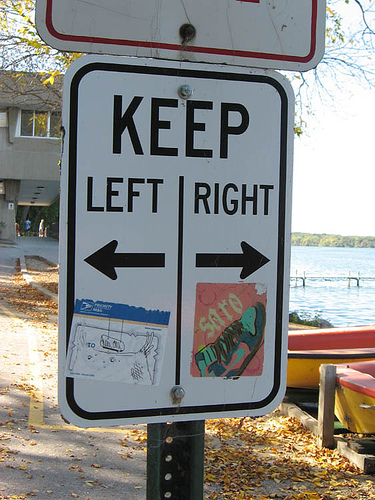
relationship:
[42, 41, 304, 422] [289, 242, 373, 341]
sign near water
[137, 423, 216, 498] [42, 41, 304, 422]
pole holding sign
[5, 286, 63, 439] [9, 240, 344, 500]
lines on ground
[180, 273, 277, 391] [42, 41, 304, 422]
sticker on sign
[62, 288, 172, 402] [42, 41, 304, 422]
sticker on sign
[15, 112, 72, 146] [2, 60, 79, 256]
window on building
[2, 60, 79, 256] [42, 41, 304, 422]
building behind sign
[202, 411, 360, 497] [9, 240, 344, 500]
leaves on ground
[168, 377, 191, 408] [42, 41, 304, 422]
bolt on sign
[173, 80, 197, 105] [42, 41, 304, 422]
bolt on sign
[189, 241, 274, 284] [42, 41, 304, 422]
arrow on sign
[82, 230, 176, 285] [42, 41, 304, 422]
arrow on sign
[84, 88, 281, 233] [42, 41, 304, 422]
letters on sign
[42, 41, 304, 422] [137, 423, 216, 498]
sign on post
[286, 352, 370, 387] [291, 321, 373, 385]
paint on boat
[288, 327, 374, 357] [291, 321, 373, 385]
paint on boat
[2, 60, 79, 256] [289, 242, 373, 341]
house on lake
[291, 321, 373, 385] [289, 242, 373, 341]
boat in water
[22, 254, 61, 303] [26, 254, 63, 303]
leaves in sand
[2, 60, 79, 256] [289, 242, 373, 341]
house by lake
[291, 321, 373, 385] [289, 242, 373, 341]
boat on lake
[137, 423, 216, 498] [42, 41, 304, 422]
pole on sign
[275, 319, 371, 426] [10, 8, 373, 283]
boats in background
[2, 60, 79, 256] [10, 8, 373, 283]
building in background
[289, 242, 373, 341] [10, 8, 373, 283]
water in background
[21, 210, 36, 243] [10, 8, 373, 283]
people in background